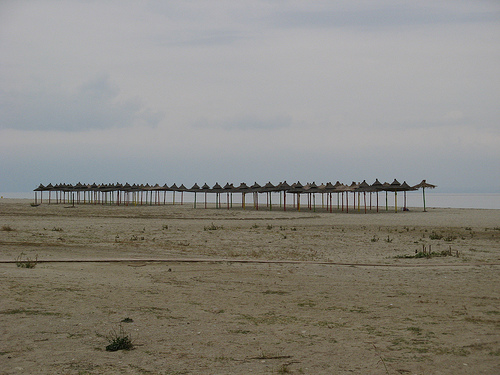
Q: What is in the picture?
A: Umbrellas.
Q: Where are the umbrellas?
A: In the ground.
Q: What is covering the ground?
A: Sand.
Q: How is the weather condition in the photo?
A: Fair.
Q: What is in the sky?
A: Clouds.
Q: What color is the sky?
A: Blue.